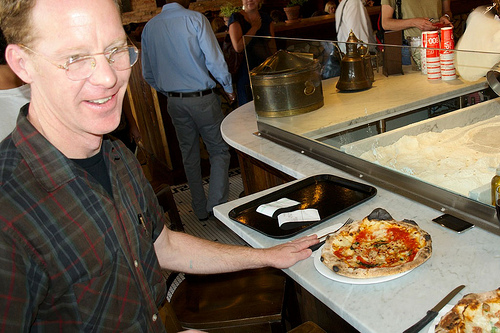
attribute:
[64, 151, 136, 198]
undershirt — black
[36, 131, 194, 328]
shirt — dark plaid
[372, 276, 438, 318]
counter — gray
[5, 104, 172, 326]
shirt — black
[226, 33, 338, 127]
tin — black, brass metal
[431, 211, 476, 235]
cell phone — black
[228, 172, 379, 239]
tray — black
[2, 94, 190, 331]
shirt — brown, blue and red, plaid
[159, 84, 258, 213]
gray pants — grey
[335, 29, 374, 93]
pitcher — black, brass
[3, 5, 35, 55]
hair — grey